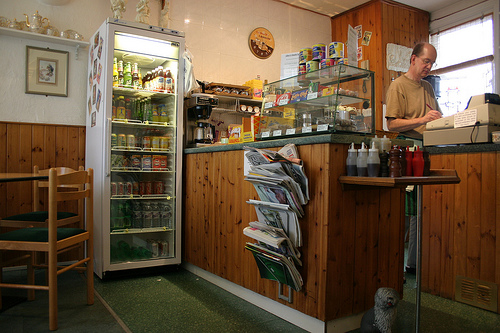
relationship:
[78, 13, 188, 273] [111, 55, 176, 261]
cooler full of drinks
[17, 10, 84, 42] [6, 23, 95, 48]
tea set on a shelf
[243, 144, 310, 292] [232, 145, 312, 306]
magazines in a rack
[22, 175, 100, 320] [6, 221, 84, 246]
chair with seat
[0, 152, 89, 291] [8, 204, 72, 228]
chair with seat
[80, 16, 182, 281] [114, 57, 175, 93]
cooler filled with drinks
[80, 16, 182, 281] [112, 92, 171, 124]
cooler filled with drinks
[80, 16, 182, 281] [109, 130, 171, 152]
cooler filled with drinks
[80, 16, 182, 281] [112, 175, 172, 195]
cooler filled with drinks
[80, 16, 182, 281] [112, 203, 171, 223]
cooler filled with drinks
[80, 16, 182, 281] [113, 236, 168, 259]
cooler filled with drinks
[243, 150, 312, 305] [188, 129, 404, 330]
rack on a counter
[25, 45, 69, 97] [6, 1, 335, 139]
drawing on a wall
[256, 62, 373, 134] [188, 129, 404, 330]
case on a counter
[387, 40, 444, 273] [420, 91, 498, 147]
man standing at a register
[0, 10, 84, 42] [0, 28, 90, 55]
tea set on a shelf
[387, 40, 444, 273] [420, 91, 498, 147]
man at register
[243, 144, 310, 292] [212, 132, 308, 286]
magazines on a rack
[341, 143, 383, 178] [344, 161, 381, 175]
bottles of syrup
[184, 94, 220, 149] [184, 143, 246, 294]
coffee maker on counter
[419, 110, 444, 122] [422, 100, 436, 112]
hand holding pencil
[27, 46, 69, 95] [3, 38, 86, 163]
drawing on wall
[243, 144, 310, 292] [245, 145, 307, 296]
magazines and magazines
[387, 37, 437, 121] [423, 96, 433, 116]
man writing with pencil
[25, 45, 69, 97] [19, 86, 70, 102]
drawing in a frame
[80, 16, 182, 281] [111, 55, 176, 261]
cooler full of drinks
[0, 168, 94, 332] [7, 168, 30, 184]
chair at table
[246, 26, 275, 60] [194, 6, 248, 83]
clock on wall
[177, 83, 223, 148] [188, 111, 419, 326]
coffee maker on counter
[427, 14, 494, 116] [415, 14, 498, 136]
window over kitchen sink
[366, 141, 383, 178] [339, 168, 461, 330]
condiment on table